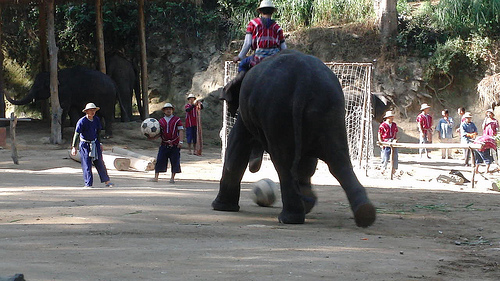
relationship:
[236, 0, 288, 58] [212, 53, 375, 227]
man on an elephant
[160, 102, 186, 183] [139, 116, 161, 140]
man holding soccer ball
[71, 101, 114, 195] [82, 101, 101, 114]
man wearing a brimmed hat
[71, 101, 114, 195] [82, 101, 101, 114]
man wearing a hat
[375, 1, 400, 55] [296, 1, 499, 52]
tree trunk on ledge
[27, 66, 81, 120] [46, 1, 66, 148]
elephants around a tree trunk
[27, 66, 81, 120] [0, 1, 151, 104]
elephants between trees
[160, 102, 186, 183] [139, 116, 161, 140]
man with soccer ball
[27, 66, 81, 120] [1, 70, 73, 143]
an elephant in shade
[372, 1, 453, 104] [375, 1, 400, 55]
roots from tree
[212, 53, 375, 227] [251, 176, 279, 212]
elephant kicking a ball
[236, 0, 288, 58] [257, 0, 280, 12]
man with a sun hat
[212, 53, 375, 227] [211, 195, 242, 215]
elephant has a large foot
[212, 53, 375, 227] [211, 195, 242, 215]
elephant has a large foot print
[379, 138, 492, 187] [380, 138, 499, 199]
table made from logs and planks